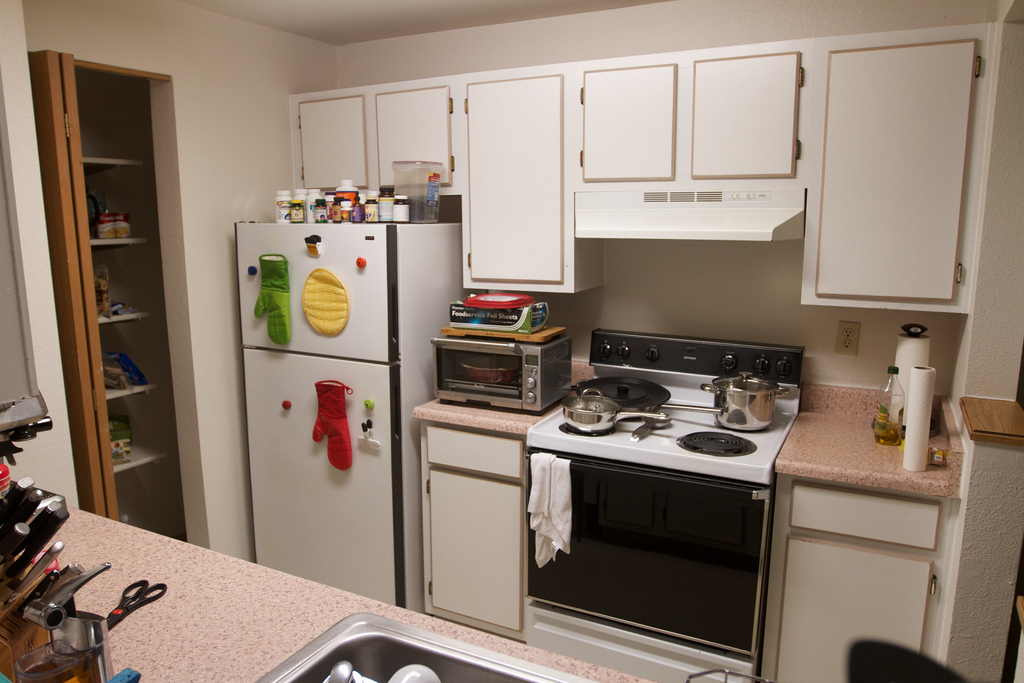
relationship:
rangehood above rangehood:
[566, 178, 807, 245] [573, 187, 806, 241]